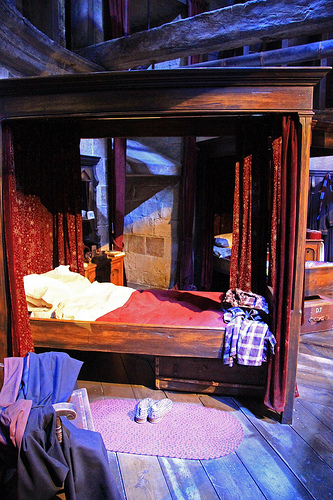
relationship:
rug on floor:
[94, 398, 242, 460] [76, 396, 331, 494]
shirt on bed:
[218, 300, 278, 372] [0, 69, 315, 427]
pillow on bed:
[16, 264, 97, 309] [0, 69, 315, 427]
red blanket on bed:
[124, 284, 230, 330] [0, 69, 315, 427]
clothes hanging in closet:
[312, 175, 332, 263] [306, 160, 330, 284]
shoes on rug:
[128, 399, 174, 426] [171, 414, 214, 447]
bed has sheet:
[16, 257, 306, 427] [37, 273, 234, 323]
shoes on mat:
[122, 397, 175, 438] [79, 394, 246, 462]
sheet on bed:
[113, 286, 234, 323] [0, 69, 315, 427]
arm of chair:
[51, 401, 76, 421] [0, 362, 102, 498]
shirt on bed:
[218, 311, 274, 372] [0, 69, 315, 427]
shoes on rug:
[147, 397, 175, 427] [94, 398, 242, 460]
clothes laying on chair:
[3, 357, 122, 498] [0, 349, 98, 497]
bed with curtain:
[0, 69, 315, 427] [260, 116, 299, 417]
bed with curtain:
[0, 69, 315, 427] [225, 119, 261, 298]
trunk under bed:
[155, 357, 264, 396] [0, 69, 315, 427]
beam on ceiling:
[73, 2, 332, 69] [7, 0, 332, 83]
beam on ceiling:
[1, 0, 106, 73] [7, 0, 332, 83]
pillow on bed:
[16, 252, 94, 312] [0, 69, 315, 427]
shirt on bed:
[218, 311, 274, 372] [12, 67, 329, 454]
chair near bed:
[0, 349, 98, 497] [0, 69, 315, 427]